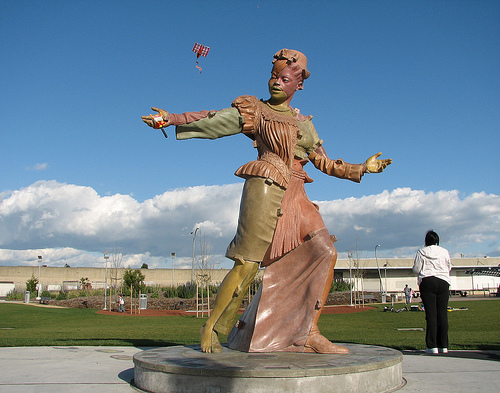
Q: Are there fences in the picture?
A: No, there are no fences.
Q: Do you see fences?
A: No, there are no fences.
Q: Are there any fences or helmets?
A: No, there are no fences or helmets.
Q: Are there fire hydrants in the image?
A: No, there are no fire hydrants.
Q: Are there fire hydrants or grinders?
A: No, there are no fire hydrants or grinders.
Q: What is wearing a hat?
A: The statue is wearing a hat.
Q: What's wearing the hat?
A: The statue is wearing a hat.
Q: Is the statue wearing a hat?
A: Yes, the statue is wearing a hat.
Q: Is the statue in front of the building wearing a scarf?
A: No, the statue is wearing a hat.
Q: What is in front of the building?
A: The statue is in front of the building.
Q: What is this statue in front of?
A: The statue is in front of the building.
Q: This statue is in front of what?
A: The statue is in front of the building.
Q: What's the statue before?
A: The statue is in front of the building.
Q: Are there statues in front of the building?
A: Yes, there is a statue in front of the building.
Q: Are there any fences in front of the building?
A: No, there is a statue in front of the building.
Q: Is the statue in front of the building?
A: Yes, the statue is in front of the building.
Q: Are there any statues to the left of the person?
A: Yes, there is a statue to the left of the person.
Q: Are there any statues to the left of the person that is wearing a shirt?
A: Yes, there is a statue to the left of the person.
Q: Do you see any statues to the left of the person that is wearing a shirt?
A: Yes, there is a statue to the left of the person.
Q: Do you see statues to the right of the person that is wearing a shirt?
A: No, the statue is to the left of the person.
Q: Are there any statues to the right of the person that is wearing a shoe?
A: No, the statue is to the left of the person.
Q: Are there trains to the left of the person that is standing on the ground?
A: No, there is a statue to the left of the person.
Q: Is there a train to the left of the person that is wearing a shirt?
A: No, there is a statue to the left of the person.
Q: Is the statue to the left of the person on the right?
A: Yes, the statue is to the left of the person.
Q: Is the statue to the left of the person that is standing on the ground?
A: Yes, the statue is to the left of the person.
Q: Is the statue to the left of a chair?
A: No, the statue is to the left of the person.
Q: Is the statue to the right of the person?
A: No, the statue is to the left of the person.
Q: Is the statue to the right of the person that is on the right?
A: No, the statue is to the left of the person.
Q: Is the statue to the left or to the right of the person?
A: The statue is to the left of the person.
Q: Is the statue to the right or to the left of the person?
A: The statue is to the left of the person.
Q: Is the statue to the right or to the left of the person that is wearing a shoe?
A: The statue is to the left of the person.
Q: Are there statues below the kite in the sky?
A: Yes, there is a statue below the kite.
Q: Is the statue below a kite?
A: Yes, the statue is below a kite.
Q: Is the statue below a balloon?
A: No, the statue is below a kite.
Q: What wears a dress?
A: The statue wears a dress.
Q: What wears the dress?
A: The statue wears a dress.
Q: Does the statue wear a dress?
A: Yes, the statue wears a dress.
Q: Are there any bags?
A: No, there are no bags.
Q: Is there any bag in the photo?
A: No, there are no bags.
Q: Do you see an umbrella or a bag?
A: No, there are no bags or umbrellas.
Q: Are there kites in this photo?
A: Yes, there is a kite.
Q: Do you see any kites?
A: Yes, there is a kite.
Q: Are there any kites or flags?
A: Yes, there is a kite.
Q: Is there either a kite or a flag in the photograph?
A: Yes, there is a kite.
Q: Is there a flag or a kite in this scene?
A: Yes, there is a kite.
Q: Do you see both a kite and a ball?
A: No, there is a kite but no balls.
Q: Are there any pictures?
A: No, there are no pictures.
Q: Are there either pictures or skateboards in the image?
A: No, there are no pictures or skateboards.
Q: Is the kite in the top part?
A: Yes, the kite is in the top of the image.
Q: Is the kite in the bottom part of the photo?
A: No, the kite is in the top of the image.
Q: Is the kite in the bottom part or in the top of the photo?
A: The kite is in the top of the image.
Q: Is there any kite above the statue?
A: Yes, there is a kite above the statue.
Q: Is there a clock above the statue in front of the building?
A: No, there is a kite above the statue.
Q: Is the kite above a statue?
A: Yes, the kite is above a statue.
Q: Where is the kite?
A: The kite is in the sky.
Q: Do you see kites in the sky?
A: Yes, there is a kite in the sky.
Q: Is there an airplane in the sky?
A: No, there is a kite in the sky.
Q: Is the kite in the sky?
A: Yes, the kite is in the sky.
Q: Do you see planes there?
A: No, there are no planes.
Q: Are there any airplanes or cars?
A: No, there are no airplanes or cars.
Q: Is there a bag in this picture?
A: No, there are no bags.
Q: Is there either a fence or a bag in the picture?
A: No, there are no bags or fences.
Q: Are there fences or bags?
A: No, there are no bags or fences.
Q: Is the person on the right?
A: Yes, the person is on the right of the image.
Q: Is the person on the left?
A: No, the person is on the right of the image.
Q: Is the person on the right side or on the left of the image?
A: The person is on the right of the image.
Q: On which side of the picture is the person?
A: The person is on the right of the image.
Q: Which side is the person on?
A: The person is on the right of the image.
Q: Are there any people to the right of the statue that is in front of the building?
A: Yes, there is a person to the right of the statue.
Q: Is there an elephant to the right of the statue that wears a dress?
A: No, there is a person to the right of the statue.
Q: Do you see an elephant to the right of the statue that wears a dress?
A: No, there is a person to the right of the statue.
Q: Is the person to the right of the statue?
A: Yes, the person is to the right of the statue.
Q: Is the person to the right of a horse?
A: No, the person is to the right of the statue.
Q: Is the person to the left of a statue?
A: No, the person is to the right of a statue.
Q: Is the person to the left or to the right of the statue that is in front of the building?
A: The person is to the right of the statue.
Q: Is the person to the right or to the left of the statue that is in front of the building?
A: The person is to the right of the statue.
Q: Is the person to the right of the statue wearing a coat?
A: No, the person is wearing a shoe.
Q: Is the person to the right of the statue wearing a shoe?
A: Yes, the person is wearing a shoe.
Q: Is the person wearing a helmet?
A: No, the person is wearing a shoe.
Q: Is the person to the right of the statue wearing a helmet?
A: No, the person is wearing a shoe.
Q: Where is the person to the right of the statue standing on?
A: The person is standing on the ground.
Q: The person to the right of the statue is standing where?
A: The person is standing on the ground.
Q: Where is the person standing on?
A: The person is standing on the ground.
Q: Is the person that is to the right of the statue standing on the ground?
A: Yes, the person is standing on the ground.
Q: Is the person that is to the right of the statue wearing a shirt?
A: Yes, the person is wearing a shirt.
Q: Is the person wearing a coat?
A: No, the person is wearing a shirt.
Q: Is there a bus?
A: No, there are no buses.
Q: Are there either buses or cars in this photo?
A: No, there are no buses or cars.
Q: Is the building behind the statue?
A: Yes, the building is behind the statue.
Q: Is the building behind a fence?
A: No, the building is behind the statue.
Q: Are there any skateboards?
A: No, there are no skateboards.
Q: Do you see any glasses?
A: No, there are no glasses.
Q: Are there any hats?
A: Yes, there is a hat.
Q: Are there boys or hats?
A: Yes, there is a hat.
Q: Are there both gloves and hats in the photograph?
A: No, there is a hat but no gloves.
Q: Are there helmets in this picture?
A: No, there are no helmets.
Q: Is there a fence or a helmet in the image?
A: No, there are no helmets or fences.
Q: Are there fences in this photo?
A: No, there are no fences.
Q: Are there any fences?
A: No, there are no fences.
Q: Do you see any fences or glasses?
A: No, there are no fences or glasses.